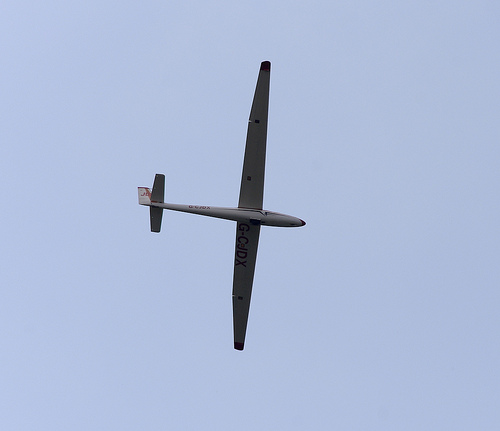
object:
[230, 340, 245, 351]
tip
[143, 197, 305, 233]
underside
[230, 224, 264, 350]
wing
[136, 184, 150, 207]
stabilizer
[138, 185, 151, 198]
markings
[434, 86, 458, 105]
clouds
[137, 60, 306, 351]
glider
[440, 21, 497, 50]
sky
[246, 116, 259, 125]
steering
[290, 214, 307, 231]
nose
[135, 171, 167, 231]
backend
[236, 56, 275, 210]
wing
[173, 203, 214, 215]
writing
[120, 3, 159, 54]
sky